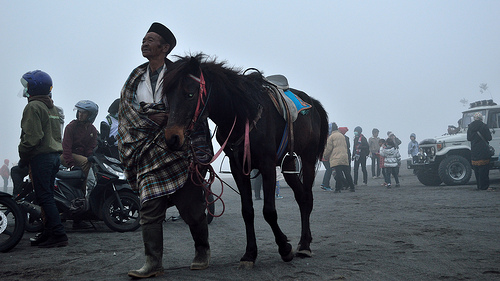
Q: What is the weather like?
A: Foggy.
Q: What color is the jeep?
A: White.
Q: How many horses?
A: 1.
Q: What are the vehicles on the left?
A: Motorcycles.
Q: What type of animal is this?
A: A horse.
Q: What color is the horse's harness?
A: Pink.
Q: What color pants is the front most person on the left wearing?
A: Blue jeans.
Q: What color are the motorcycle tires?
A: Black.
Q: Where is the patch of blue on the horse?
A: The saddle.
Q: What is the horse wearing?
A: A saddle.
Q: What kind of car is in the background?
A: Jeep.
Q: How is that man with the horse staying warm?
A: A blanket.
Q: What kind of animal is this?
A: Horse.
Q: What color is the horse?
A: Brown.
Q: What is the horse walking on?
A: Dirt ground.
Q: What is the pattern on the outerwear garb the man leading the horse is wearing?
A: Plaid.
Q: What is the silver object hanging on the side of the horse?
A: Foot saddle place hold.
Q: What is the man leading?
A: A horse.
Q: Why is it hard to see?
A: Cloudy.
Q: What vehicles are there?
A: Truck and motorbikes.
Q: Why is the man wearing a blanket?
A: It's cold.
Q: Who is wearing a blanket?
A: The man with the horse.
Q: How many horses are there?
A: One.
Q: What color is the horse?
A: Brown.